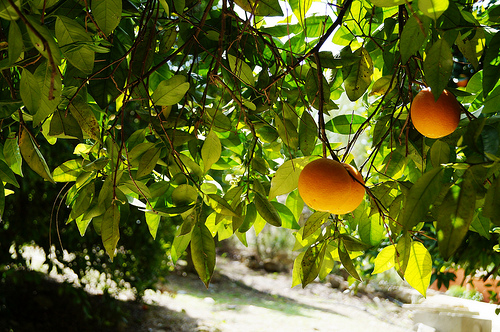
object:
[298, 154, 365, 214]
orange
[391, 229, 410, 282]
leaves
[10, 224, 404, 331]
road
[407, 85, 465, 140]
orange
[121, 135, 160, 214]
branch